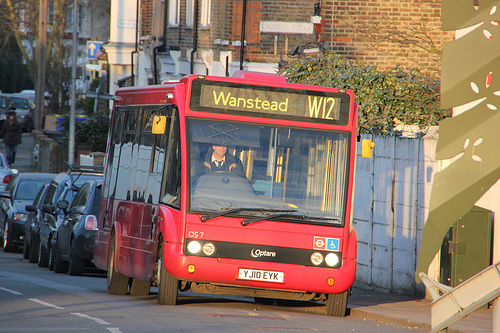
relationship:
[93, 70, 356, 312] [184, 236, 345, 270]
bus has light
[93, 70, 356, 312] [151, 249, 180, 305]
bus has tire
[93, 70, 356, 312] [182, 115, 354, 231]
bus has window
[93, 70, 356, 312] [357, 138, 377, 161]
bus has mirror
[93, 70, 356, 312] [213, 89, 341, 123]
bus has letter